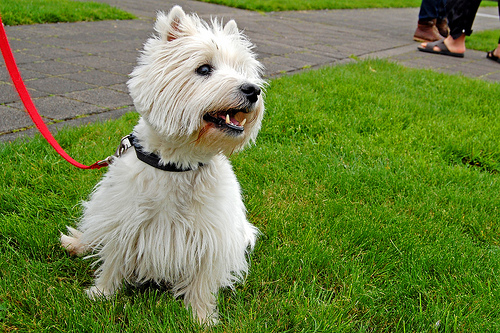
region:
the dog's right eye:
[187, 59, 215, 79]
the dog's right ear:
[155, 1, 197, 48]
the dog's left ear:
[215, 14, 243, 44]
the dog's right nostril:
[241, 81, 254, 97]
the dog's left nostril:
[256, 84, 262, 97]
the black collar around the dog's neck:
[127, 127, 209, 179]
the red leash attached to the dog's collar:
[0, 11, 132, 181]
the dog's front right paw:
[81, 270, 122, 308]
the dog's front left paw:
[178, 289, 228, 329]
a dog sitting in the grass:
[44, 3, 291, 329]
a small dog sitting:
[50, 4, 301, 314]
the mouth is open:
[180, 90, 270, 150]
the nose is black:
[229, 71, 266, 106]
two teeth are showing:
[204, 108, 255, 135]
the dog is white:
[51, 1, 319, 321]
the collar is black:
[130, 135, 206, 182]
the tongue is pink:
[210, 107, 247, 133]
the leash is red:
[3, 0, 120, 174]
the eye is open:
[173, 49, 223, 85]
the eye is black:
[172, 40, 222, 87]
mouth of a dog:
[203, 102, 267, 133]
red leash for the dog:
[1, 27, 98, 182]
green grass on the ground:
[303, 101, 498, 326]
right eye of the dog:
[192, 56, 215, 77]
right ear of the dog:
[154, 6, 196, 41]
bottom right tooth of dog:
[221, 108, 232, 128]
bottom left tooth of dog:
[235, 110, 247, 130]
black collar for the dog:
[124, 130, 209, 189]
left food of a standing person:
[418, 39, 475, 64]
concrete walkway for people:
[13, 23, 110, 113]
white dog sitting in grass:
[59, 20, 254, 332]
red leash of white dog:
[1, 31, 123, 189]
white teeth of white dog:
[224, 106, 245, 128]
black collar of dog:
[133, 135, 194, 181]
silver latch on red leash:
[92, 135, 131, 168]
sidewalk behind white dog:
[9, 2, 499, 112]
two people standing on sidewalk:
[407, 5, 496, 61]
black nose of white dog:
[237, 80, 286, 97]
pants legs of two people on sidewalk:
[412, 2, 498, 34]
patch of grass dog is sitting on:
[14, 59, 489, 326]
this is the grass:
[311, 75, 388, 221]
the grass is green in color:
[283, 186, 408, 283]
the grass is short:
[290, 172, 448, 299]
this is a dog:
[71, 13, 262, 303]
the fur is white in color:
[113, 189, 201, 251]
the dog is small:
[48, 0, 282, 326]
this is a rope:
[5, 53, 110, 183]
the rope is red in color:
[13, 69, 90, 171]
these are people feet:
[413, 4, 498, 61]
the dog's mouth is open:
[203, 100, 253, 137]